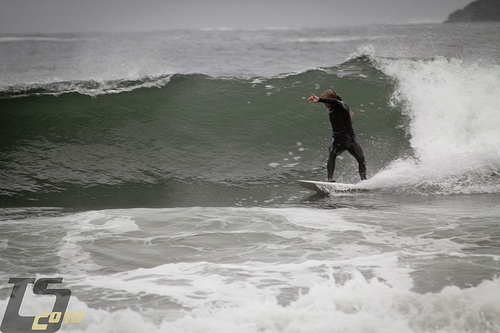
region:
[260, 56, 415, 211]
man surfing a large wave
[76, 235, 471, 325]
white top of crashing wave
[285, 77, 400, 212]
man surfing in wet suit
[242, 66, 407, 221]
man standing on top of a surf board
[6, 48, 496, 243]
big ocean wave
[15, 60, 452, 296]
rough ocean water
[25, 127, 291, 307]
grey ocean water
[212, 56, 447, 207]
surfer hanging ten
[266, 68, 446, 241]
surfer shredding waves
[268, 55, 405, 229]
man balancing on surfboard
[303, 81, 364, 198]
this is a man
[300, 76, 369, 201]
the man is surfing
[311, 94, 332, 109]
the left hand is on air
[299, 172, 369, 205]
this is a surf board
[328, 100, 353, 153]
the costumes are black in color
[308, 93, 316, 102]
the man is light skinned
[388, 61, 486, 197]
the waves are strong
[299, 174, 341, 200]
the surf board is white in color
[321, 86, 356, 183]
the man is wet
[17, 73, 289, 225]
the water is green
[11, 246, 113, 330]
photographers water mark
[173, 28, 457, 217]
surfing person in all black gear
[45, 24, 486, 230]
large waves of water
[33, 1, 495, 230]
man surfing large waves off a beach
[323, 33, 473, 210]
water spray from waves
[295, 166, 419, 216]
white surf board in water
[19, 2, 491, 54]
grey murky skies behind raging water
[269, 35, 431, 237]
man enjoying waves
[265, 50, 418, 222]
blond man surfing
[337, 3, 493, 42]
land in the distance behind water full of waves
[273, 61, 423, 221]
Surfer on the wave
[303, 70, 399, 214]
Surfer wearing a wet suit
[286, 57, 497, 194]
White water on the waves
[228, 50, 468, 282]
Surfer in the ocean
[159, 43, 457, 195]
Surfboard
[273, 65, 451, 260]
Surfer with arm in the air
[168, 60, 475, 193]
Large wave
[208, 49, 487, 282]
Large waves in the ocean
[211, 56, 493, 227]
Surfing on the beach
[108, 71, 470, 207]
Catching waves in the ocean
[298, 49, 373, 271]
Riding waves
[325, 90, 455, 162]
White water from the waves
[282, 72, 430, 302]
A black wetsuit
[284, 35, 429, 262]
Surfer wearing a wet suit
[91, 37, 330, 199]
Large waves in the ocean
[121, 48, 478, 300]
Ocean waves with a surfer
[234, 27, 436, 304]
A guy on the surfboard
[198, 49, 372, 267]
A large wave with a surfer riding it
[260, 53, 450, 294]
Surfboard